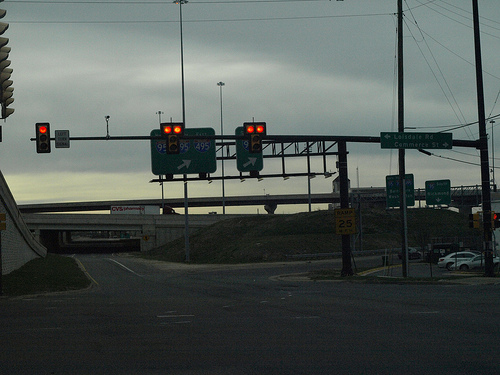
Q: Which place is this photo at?
A: It is at the road.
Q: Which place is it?
A: It is a road.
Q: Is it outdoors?
A: Yes, it is outdoors.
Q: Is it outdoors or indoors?
A: It is outdoors.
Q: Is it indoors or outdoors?
A: It is outdoors.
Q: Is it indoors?
A: No, it is outdoors.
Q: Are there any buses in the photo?
A: No, there are no buses.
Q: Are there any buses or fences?
A: No, there are no buses or fences.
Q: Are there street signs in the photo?
A: Yes, there is a street sign.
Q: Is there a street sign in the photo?
A: Yes, there is a street sign.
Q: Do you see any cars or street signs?
A: Yes, there is a street sign.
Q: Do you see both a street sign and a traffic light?
A: Yes, there are both a street sign and a traffic light.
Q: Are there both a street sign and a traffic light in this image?
A: Yes, there are both a street sign and a traffic light.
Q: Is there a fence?
A: No, there are no fences.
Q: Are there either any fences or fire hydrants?
A: No, there are no fences or fire hydrants.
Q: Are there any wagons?
A: No, there are no wagons.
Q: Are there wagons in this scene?
A: No, there are no wagons.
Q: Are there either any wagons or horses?
A: No, there are no wagons or horses.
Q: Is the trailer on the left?
A: Yes, the trailer is on the left of the image.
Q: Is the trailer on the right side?
A: No, the trailer is on the left of the image.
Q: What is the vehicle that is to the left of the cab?
A: The vehicle is a trailer.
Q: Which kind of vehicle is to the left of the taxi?
A: The vehicle is a trailer.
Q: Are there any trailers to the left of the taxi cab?
A: Yes, there is a trailer to the left of the taxi cab.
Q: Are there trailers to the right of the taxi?
A: No, the trailer is to the left of the taxi.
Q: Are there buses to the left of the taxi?
A: No, there is a trailer to the left of the taxi.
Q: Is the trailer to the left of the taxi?
A: Yes, the trailer is to the left of the taxi.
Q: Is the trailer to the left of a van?
A: No, the trailer is to the left of the taxi.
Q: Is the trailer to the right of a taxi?
A: No, the trailer is to the left of a taxi.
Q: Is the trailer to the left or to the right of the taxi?
A: The trailer is to the left of the taxi.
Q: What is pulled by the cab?
A: The trailer is pulled by the cab.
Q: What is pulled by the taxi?
A: The trailer is pulled by the cab.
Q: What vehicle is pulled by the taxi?
A: The vehicle is a trailer.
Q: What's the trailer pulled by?
A: The trailer is pulled by the cab.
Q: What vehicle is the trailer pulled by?
A: The trailer is pulled by the taxi.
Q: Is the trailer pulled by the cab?
A: Yes, the trailer is pulled by the cab.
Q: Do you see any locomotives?
A: No, there are no locomotives.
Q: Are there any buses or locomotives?
A: No, there are no locomotives or buses.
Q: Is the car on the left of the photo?
A: No, the car is on the right of the image.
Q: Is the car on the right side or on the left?
A: The car is on the right of the image.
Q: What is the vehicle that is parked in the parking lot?
A: The vehicle is a car.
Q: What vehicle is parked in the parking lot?
A: The vehicle is a car.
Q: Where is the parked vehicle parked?
A: The car is parked in the parking lot.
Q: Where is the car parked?
A: The car is parked in the parking lot.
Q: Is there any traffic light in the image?
A: Yes, there is a traffic light.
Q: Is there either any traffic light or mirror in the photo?
A: Yes, there is a traffic light.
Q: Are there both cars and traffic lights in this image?
A: Yes, there are both a traffic light and a car.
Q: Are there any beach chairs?
A: No, there are no beach chairs.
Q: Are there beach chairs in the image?
A: No, there are no beach chairs.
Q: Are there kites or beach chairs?
A: No, there are no beach chairs or kites.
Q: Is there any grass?
A: Yes, there is grass.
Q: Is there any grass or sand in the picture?
A: Yes, there is grass.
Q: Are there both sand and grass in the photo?
A: No, there is grass but no sand.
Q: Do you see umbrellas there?
A: No, there are no umbrellas.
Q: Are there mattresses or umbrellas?
A: No, there are no umbrellas or mattresses.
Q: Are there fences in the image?
A: No, there are no fences.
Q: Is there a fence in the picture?
A: No, there are no fences.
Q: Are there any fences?
A: No, there are no fences.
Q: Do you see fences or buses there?
A: No, there are no fences or buses.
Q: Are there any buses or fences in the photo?
A: No, there are no fences or buses.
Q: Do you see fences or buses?
A: No, there are no fences or buses.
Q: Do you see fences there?
A: No, there are no fences.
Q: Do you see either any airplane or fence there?
A: No, there are no fences or airplanes.